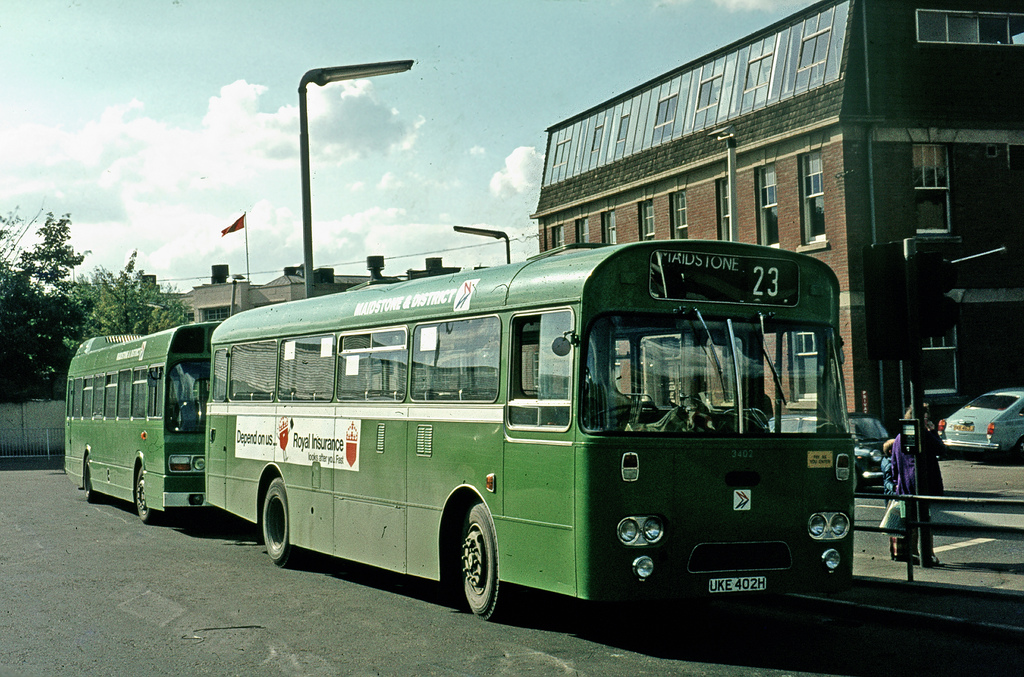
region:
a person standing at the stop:
[892, 359, 954, 676]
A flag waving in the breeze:
[169, 186, 310, 311]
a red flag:
[205, 190, 266, 279]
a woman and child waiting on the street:
[878, 383, 946, 576]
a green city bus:
[183, 226, 873, 622]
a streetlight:
[243, 21, 443, 281]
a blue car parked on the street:
[934, 359, 1023, 473]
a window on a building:
[789, 137, 840, 259]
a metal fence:
[855, 476, 1021, 612]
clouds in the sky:
[50, 61, 425, 202]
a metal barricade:
[0, 418, 68, 472]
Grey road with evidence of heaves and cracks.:
[73, 501, 397, 675]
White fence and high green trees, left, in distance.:
[2, 191, 92, 468]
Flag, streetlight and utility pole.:
[209, 101, 511, 251]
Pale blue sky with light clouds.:
[118, 112, 467, 248]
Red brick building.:
[539, 105, 1017, 380]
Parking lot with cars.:
[838, 371, 1022, 559]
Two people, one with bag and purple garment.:
[882, 392, 950, 585]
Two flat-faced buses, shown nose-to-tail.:
[76, 231, 857, 633]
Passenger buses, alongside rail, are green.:
[48, 245, 1019, 619]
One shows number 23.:
[721, 244, 859, 369]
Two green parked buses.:
[64, 238, 855, 618]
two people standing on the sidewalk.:
[879, 403, 941, 563]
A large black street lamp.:
[296, 59, 413, 297]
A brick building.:
[533, 1, 1021, 412]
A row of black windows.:
[544, 0, 842, 187]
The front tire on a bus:
[441, 494, 505, 616]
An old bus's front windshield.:
[580, 305, 849, 435]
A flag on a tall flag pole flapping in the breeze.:
[219, 210, 251, 281]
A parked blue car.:
[936, 384, 1022, 452]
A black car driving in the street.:
[768, 408, 892, 482]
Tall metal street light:
[267, 33, 435, 286]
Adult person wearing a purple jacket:
[889, 392, 950, 571]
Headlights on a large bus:
[607, 512, 680, 579]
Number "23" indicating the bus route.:
[728, 261, 799, 300]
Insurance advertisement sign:
[225, 413, 378, 471]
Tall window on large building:
[892, 127, 963, 248]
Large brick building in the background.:
[529, 4, 1021, 454]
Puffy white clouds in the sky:
[0, 59, 554, 212]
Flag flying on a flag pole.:
[203, 209, 280, 276]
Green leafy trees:
[0, 213, 216, 420]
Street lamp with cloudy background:
[271, 44, 433, 196]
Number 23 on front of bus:
[738, 246, 814, 310]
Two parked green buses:
[56, 232, 863, 622]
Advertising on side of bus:
[185, 351, 402, 501]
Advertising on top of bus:
[294, 271, 541, 336]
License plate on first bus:
[673, 532, 833, 615]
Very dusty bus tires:
[176, 431, 540, 631]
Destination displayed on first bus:
[628, 215, 747, 291]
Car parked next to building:
[915, 355, 1023, 464]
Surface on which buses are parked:
[31, 528, 316, 674]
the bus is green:
[219, 316, 843, 610]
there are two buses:
[49, 293, 811, 642]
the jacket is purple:
[886, 422, 957, 515]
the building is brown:
[513, 208, 978, 289]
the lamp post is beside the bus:
[273, 44, 463, 317]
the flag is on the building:
[201, 188, 266, 266]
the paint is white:
[216, 401, 400, 485]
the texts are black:
[230, 420, 345, 450]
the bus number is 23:
[720, 258, 804, 303]